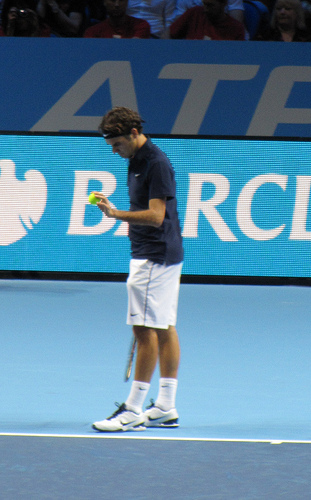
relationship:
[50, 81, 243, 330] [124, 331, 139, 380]
athlete has racket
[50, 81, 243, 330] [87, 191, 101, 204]
athlete has ball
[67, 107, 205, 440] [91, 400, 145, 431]
man wearing shoe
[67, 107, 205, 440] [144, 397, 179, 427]
man wearing shoe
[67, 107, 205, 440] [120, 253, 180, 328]
man wearing shorts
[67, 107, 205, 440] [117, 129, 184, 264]
man wearing blue shirt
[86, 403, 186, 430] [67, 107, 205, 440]
shoes on man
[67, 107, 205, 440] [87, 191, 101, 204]
man holding ball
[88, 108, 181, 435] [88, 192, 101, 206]
player about to bounce ball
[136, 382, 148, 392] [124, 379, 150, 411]
logo on sock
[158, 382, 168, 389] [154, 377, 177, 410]
logo on sock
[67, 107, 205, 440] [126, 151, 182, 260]
man wearing blue shirt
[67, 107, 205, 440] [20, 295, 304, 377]
man standing on court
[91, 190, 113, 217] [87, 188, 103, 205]
hand holding tennis ball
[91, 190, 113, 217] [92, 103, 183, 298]
hand on player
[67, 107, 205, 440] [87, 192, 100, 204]
man holding tennis ball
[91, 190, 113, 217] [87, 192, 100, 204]
hand holding tennis ball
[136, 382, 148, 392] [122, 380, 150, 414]
logo on sock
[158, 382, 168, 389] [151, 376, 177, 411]
logo on sock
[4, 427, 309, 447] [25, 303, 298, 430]
white line on blue court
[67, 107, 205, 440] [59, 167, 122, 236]
man holding ball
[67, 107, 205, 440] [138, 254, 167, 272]
man carrying tennis ball in pocket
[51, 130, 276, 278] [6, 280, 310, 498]
sign in back of tennis court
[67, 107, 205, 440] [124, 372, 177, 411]
man wearing nike socks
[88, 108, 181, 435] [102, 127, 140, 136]
player wearing headband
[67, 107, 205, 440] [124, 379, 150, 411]
man wearing sock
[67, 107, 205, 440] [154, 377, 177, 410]
man wearing sock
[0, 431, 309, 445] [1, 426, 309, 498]
line on court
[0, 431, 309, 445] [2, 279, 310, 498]
line on court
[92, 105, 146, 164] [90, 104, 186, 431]
head of tennis player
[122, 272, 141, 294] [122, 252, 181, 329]
bulge in short pants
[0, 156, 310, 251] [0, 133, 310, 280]
logo on wall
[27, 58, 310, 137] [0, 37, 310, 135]
white logo on blue wall